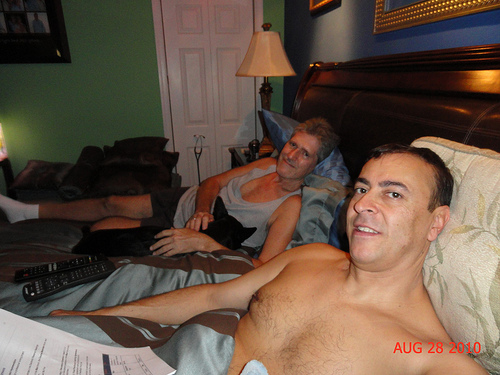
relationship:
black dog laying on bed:
[69, 194, 257, 258] [1, 42, 498, 373]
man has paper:
[51, 145, 487, 372] [0, 309, 177, 375]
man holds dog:
[146, 113, 336, 234] [55, 221, 303, 282]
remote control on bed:
[22, 259, 113, 301] [1, 42, 498, 373]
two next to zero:
[446, 339, 456, 356] [473, 338, 480, 357]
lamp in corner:
[233, 24, 295, 157] [263, 0, 298, 117]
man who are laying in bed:
[51, 145, 487, 372] [423, 195, 473, 275]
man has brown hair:
[51, 145, 487, 372] [372, 144, 454, 207]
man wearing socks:
[51, 145, 487, 372] [21, 210, 93, 277]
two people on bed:
[9, 121, 468, 370] [18, 76, 496, 368]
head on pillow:
[324, 137, 462, 282] [432, 142, 500, 359]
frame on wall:
[0, 1, 72, 66] [1, 4, 281, 170]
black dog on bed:
[69, 194, 257, 258] [1, 42, 498, 373]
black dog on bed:
[52, 194, 257, 291] [1, 42, 498, 373]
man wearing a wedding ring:
[0, 113, 329, 258] [194, 215, 198, 220]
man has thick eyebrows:
[51, 145, 487, 372] [371, 176, 403, 189]